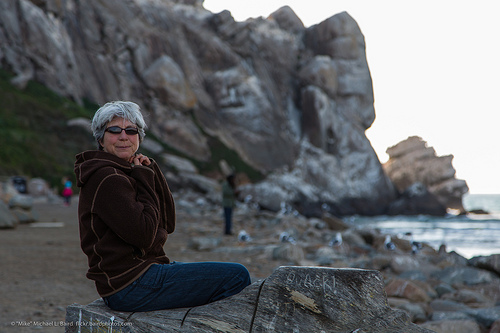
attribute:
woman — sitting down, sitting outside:
[71, 100, 254, 311]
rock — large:
[65, 263, 420, 330]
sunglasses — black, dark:
[101, 123, 141, 136]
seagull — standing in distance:
[382, 234, 396, 251]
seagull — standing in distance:
[409, 237, 425, 258]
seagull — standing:
[327, 227, 347, 248]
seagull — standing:
[276, 229, 296, 246]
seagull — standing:
[234, 228, 254, 243]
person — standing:
[218, 171, 248, 235]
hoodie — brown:
[72, 148, 177, 297]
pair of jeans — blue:
[102, 261, 253, 313]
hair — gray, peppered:
[90, 100, 150, 147]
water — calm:
[339, 208, 499, 256]